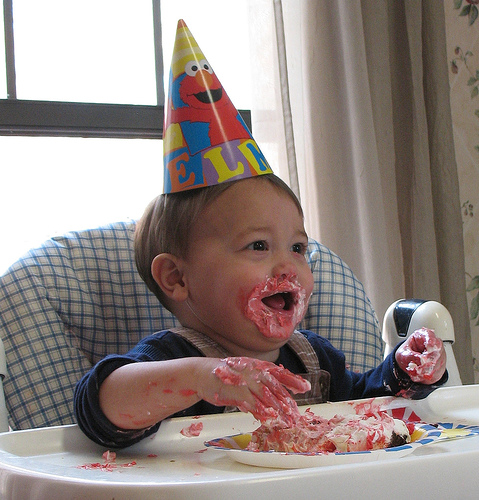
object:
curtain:
[305, 0, 479, 387]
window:
[1, 2, 307, 267]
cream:
[241, 279, 305, 334]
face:
[188, 183, 317, 345]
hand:
[205, 347, 308, 424]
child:
[74, 172, 447, 448]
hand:
[394, 325, 446, 386]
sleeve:
[71, 333, 208, 439]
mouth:
[259, 286, 299, 318]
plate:
[205, 403, 436, 472]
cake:
[246, 403, 411, 454]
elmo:
[164, 62, 256, 152]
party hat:
[154, 16, 277, 197]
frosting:
[85, 399, 234, 479]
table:
[0, 377, 477, 499]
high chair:
[3, 211, 478, 499]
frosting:
[167, 351, 319, 425]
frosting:
[409, 332, 437, 383]